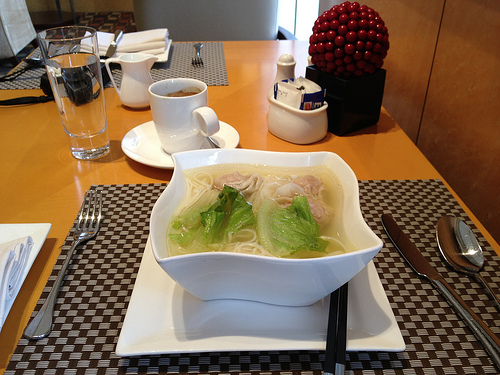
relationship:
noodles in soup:
[218, 230, 264, 255] [169, 162, 356, 258]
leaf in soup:
[259, 195, 327, 255] [169, 162, 356, 258]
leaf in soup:
[172, 181, 256, 246] [169, 162, 356, 258]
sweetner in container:
[274, 77, 326, 109] [269, 98, 328, 146]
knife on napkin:
[105, 29, 126, 58] [121, 28, 171, 60]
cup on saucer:
[150, 77, 220, 153] [122, 121, 175, 175]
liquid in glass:
[46, 50, 107, 137] [35, 26, 111, 162]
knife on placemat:
[380, 208, 499, 367] [7, 183, 162, 375]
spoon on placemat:
[435, 213, 500, 325] [7, 183, 162, 375]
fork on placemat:
[24, 191, 104, 340] [7, 183, 162, 375]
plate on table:
[114, 288, 407, 357] [0, 87, 123, 224]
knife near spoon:
[380, 208, 499, 367] [435, 213, 500, 325]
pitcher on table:
[107, 51, 158, 110] [0, 87, 123, 224]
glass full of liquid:
[35, 26, 111, 162] [46, 50, 107, 137]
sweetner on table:
[274, 77, 326, 109] [0, 87, 123, 224]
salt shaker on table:
[274, 55, 296, 87] [0, 87, 123, 224]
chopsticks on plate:
[326, 283, 350, 374] [114, 288, 407, 357]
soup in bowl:
[169, 162, 356, 258] [151, 249, 381, 308]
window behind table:
[277, 1, 319, 41] [0, 87, 123, 224]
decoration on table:
[306, 1, 390, 134] [0, 87, 123, 224]